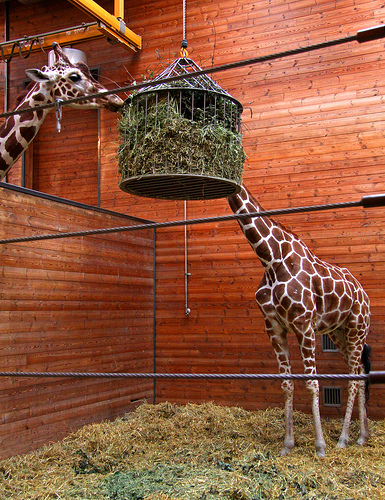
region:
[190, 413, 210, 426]
part of a grass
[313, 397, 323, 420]
front leg of a giraffe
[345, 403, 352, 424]
back leg of a giraffe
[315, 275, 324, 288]
body of a giraffe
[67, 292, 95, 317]
section of a wooden wall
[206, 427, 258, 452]
food for the giraffe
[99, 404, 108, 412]
bottom of a ranch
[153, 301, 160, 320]
corner of a wall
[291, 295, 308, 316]
front limb of a giraffe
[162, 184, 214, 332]
metal pipe on the wall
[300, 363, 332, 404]
giraffe knee that is knobby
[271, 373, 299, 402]
giraffe knee that is knobby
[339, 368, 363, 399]
giraffe knee that is knobby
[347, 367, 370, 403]
giraffe knee that is knobby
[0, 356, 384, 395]
a large wire rope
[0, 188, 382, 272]
a large wire rope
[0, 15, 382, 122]
a large wire rope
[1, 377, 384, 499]
the ground is covered in hay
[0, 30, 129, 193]
head and neck of a giraffe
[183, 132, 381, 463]
a giraffe in a pen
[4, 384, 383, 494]
ground covered in hay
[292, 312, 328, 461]
long leg of a giraffe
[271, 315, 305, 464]
long leg of a giraffe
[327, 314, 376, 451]
long leg of a giraffe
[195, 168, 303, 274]
neck of a giraffe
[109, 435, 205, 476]
The background is orange.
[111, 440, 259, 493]
The background is orange.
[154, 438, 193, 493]
The background is orange.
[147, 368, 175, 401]
The background is orange.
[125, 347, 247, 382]
The background is orange.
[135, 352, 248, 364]
The background is orange.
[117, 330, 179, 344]
The background is orange.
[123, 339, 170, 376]
The background is orange.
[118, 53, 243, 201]
The basket is metal.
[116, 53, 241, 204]
The basket is black.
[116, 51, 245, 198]
Grass in the basket.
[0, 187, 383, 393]
The fence is metal.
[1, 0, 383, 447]
The wall is wooden.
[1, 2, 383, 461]
The walls are brown.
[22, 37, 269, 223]
Two giraffes eating grass.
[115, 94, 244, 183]
The grass is green.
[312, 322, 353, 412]
Two vents on the wall.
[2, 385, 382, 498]
The hay is brown.